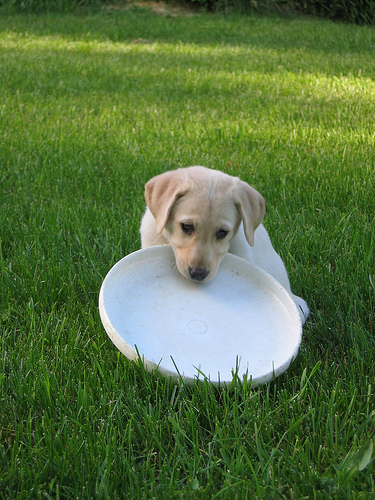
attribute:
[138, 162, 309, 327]
dog — sitting, playing, looking, wanting, young, enjoying, white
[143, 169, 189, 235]
ear — brown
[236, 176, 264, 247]
ear — brown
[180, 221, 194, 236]
eye — dark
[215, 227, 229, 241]
eye — dark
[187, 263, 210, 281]
nose — black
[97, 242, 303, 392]
frisbee — white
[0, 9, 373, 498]
grass — green, thick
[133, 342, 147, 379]
blade — green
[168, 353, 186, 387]
blade — green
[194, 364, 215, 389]
blade — green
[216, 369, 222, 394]
blade — green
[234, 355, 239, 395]
blade — green